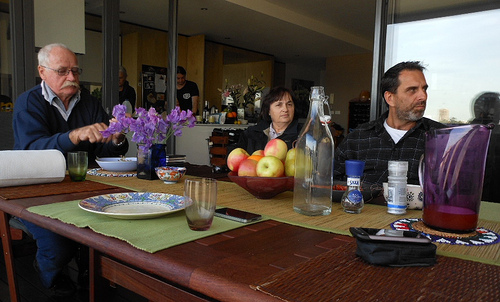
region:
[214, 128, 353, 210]
bowl of fruit on counter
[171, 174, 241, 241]
empty glass on counter by plate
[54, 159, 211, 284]
green place mat on counter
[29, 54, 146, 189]
man in blue shirt at counter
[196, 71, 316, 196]
woman at counter in black shirt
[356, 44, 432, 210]
man in plaid shirt at counter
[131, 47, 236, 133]
woman in background in black shirt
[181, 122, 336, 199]
apples on counter top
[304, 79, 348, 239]
empty caraffe on counter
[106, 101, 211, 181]
purple flowers in vase on counter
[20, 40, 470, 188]
three people at the table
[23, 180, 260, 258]
blue and white plate next to glass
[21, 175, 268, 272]
cell phone next to glass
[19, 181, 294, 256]
green placemat under dinner plate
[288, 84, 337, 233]
empty clear glass bottle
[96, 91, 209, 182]
purple flowers on dining table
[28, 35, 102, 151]
man wearing wire rim glasses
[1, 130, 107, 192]
white paper towels next to green glass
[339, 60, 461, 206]
person with white shirt under blue shirt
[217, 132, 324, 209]
apples in wooden bowl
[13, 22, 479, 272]
Three People Eating a Meal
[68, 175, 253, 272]
A placesetting with plate and cup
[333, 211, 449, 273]
Cellphone on the Table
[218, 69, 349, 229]
A woman with apples and bottle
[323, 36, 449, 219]
Man with a Greying Beard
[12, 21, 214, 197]
Old man and purple flowers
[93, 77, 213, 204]
A display of purple flowers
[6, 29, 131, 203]
Old man with white hair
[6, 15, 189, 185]
Old man with blue sweater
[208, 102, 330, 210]
Bowl of Yellow and Red Apples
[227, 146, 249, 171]
yellow and red shiny apple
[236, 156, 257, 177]
yellow and red shiny apple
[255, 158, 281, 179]
yellow and red shiny apple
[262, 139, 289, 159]
yellow and red shiny apple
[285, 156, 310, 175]
yellow and red shiny apple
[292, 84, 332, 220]
empty glass bottle with stopper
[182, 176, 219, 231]
empty drink glass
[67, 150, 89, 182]
empty drink glass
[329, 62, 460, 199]
man with black and gray beard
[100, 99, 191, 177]
blue glass vase with purple flowers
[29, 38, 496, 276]
three people sitting down at a table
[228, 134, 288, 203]
a bowl of fresh fruit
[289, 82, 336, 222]
a tall empty bottle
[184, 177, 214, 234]
a drinking glass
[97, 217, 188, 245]
a placemat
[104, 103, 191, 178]
a small vase of purple flowers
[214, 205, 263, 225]
a phone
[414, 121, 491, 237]
a pitcher of juice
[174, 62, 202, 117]
a person standing in the kitchen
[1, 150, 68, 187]
a roll of paper towels